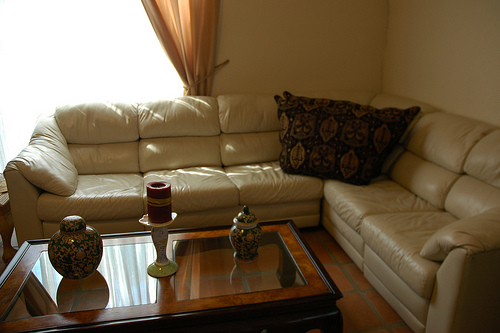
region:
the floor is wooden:
[333, 301, 342, 312]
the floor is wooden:
[352, 294, 365, 314]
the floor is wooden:
[364, 314, 376, 331]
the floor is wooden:
[362, 280, 373, 315]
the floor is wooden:
[359, 308, 371, 329]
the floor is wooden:
[355, 300, 365, 321]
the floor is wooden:
[359, 305, 368, 322]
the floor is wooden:
[360, 305, 365, 319]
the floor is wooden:
[350, 308, 360, 329]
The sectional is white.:
[18, 105, 475, 275]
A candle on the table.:
[133, 171, 194, 280]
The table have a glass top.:
[13, 222, 308, 309]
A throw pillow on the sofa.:
[269, 95, 415, 194]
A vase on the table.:
[18, 208, 118, 301]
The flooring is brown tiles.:
[322, 235, 402, 332]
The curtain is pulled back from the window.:
[135, 3, 262, 97]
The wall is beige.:
[248, 10, 386, 87]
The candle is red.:
[126, 171, 192, 226]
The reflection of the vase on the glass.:
[38, 270, 147, 311]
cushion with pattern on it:
[269, 72, 441, 220]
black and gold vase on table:
[14, 194, 121, 321]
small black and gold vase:
[203, 190, 318, 292]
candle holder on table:
[109, 167, 202, 314]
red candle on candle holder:
[118, 155, 200, 229]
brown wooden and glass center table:
[8, 220, 340, 332]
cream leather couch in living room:
[0, 78, 499, 330]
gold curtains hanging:
[138, 0, 258, 98]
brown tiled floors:
[328, 246, 404, 330]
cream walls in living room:
[245, 2, 413, 101]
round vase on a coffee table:
[39, 206, 124, 295]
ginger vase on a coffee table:
[222, 191, 288, 277]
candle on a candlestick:
[132, 168, 198, 293]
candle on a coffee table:
[131, 168, 201, 289]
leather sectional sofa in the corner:
[109, 78, 462, 241]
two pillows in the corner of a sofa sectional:
[250, 71, 445, 200]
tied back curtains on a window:
[134, 0, 244, 121]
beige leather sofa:
[47, 92, 315, 191]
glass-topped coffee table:
[25, 231, 325, 318]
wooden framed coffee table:
[10, 224, 359, 322]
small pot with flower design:
[37, 205, 114, 291]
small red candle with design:
[136, 168, 179, 228]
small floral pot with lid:
[221, 200, 274, 266]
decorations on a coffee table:
[3, 170, 355, 327]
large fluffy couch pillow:
[258, 72, 438, 207]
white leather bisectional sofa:
[3, 97, 497, 327]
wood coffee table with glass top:
[5, 222, 363, 332]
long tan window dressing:
[128, 2, 247, 106]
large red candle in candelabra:
[122, 170, 195, 293]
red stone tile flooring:
[302, 224, 407, 331]